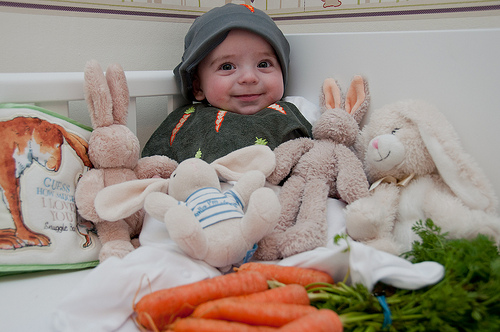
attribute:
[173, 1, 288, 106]
grey hat — grey  , orange 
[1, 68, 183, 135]
headboard — white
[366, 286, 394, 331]
tie — blue 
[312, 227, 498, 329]
tops — green 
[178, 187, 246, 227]
white shirt — blue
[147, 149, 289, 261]
stuffed animal — white , striped 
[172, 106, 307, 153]
costume — carrot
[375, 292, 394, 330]
rubber bands — blue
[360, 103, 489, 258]
rabbit — white , tan 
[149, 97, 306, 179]
white bib — green  , white   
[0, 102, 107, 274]
bib — knitted 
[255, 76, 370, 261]
animal — stuffed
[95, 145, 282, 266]
animal — stuffed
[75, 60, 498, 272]
bunnies — stuffed 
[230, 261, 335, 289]
carrots — raw, orange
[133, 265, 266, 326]
carrots — raw, orange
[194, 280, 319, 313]
carrots — raw, orange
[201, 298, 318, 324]
carrots — raw, orange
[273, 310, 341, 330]
carrots — raw, orange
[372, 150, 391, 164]
smile — sweet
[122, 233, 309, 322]
carrots — orange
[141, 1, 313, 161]
baby — smiling 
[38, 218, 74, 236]
letters — black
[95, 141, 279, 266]
bunny — stuffed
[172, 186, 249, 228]
shirt — striped, blue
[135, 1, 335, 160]
baby — sitting 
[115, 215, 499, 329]
carrots — orange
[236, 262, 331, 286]
carrot — real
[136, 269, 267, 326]
carrot — real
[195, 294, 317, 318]
carrot — real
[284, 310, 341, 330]
carrot — real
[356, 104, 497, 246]
bunny — stuffed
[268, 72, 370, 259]
bunny — stuffed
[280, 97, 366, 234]
stuffed rabbit — stuffed 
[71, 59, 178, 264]
bunny rabbit — stuffed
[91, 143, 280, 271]
bunny rabbit — stuffed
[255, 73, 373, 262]
bunny rabbit — stuffed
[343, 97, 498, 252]
bunny rabbit — stuffed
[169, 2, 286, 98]
hat — gray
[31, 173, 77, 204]
letters — blue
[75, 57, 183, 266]
animal — stuffed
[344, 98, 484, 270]
animal — stuffed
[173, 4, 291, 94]
cap — carrot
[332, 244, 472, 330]
tops — green  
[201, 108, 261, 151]
bib — grey  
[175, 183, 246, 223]
shirt — blue 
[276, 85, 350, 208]
rabbit — white   , orange  